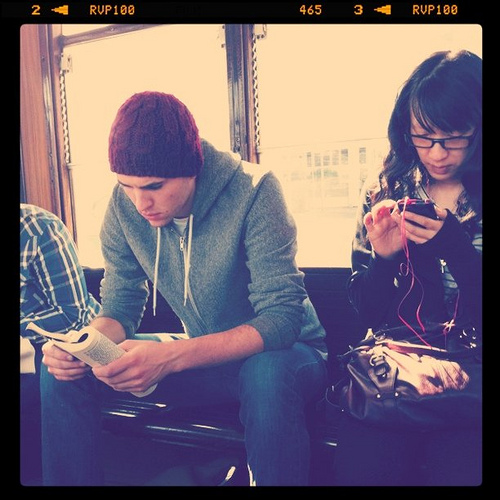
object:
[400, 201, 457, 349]
earbud cord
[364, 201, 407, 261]
hands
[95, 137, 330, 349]
shirt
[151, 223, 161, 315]
string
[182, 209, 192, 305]
string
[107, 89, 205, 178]
hat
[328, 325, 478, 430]
purse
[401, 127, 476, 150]
glasses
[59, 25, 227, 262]
window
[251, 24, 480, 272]
window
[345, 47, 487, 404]
girl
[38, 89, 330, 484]
man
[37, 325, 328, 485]
jeans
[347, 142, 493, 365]
shirt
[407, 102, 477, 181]
face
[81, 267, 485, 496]
bench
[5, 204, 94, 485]
passenger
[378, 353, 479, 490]
woman's lap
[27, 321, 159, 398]
book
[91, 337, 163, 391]
hand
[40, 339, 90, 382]
hand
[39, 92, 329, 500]
guy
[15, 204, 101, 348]
shirt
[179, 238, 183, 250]
zipper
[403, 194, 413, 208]
headphone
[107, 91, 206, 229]
head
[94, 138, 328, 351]
hoodie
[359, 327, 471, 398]
lap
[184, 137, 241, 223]
hood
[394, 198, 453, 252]
hand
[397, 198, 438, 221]
cellphone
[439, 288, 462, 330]
string